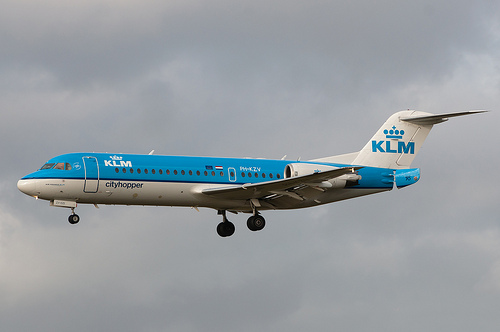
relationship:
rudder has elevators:
[403, 113, 477, 123] [419, 117, 453, 130]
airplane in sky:
[27, 105, 486, 236] [1, 10, 499, 330]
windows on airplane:
[137, 168, 143, 176] [27, 105, 486, 236]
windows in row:
[137, 168, 143, 176] [114, 167, 228, 180]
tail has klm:
[308, 87, 491, 166] [371, 139, 416, 155]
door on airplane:
[82, 158, 104, 194] [27, 105, 486, 236]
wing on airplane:
[201, 165, 356, 208] [27, 105, 486, 236]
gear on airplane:
[62, 201, 268, 237] [27, 105, 486, 236]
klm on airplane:
[371, 139, 416, 155] [27, 105, 486, 236]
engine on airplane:
[283, 163, 364, 187] [27, 105, 486, 236]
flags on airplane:
[91, 205, 205, 210] [27, 105, 486, 236]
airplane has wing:
[27, 105, 486, 236] [201, 165, 356, 208]